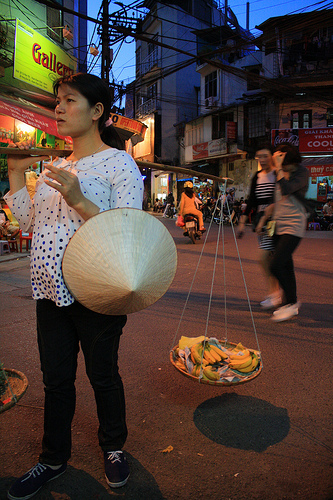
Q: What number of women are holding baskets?
A: One.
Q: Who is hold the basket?
A: The woman.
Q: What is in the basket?
A: Bananas.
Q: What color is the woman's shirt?
A: White.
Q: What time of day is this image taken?
A: Evening.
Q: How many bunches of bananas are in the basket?
A: Three.